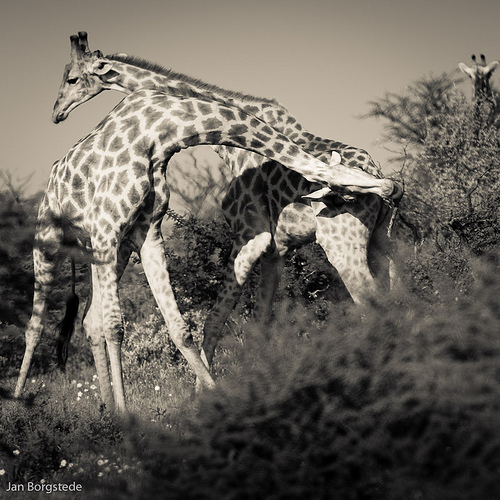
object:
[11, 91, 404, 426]
giraffe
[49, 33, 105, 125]
head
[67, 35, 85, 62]
horn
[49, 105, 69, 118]
mouth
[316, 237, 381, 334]
leg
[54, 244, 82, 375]
tail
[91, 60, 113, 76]
ear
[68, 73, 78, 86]
eye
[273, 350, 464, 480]
bush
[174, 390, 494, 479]
field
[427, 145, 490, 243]
tree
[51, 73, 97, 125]
face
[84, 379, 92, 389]
flowers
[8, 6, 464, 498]
photo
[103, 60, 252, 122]
neck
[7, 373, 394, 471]
wild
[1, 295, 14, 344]
vegetation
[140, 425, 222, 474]
grass